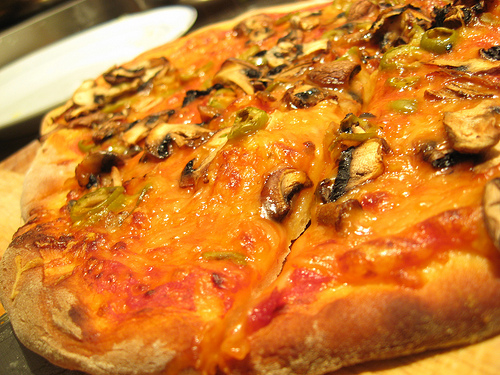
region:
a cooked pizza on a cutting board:
[26, 2, 496, 372]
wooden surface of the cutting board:
[378, 357, 497, 371]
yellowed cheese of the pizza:
[144, 192, 255, 300]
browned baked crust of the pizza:
[243, 289, 499, 353]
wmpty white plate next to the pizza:
[1, 3, 191, 111]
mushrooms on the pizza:
[261, 108, 499, 211]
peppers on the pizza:
[376, 25, 464, 104]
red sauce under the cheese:
[83, 251, 218, 320]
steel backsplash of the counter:
[0, 10, 88, 49]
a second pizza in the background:
[22, 18, 335, 143]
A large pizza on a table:
[21, 21, 471, 338]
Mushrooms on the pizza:
[18, 24, 478, 372]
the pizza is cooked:
[35, 21, 483, 363]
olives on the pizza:
[24, 81, 302, 202]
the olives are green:
[217, 114, 271, 141]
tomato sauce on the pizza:
[161, 241, 316, 316]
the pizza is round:
[51, 53, 498, 340]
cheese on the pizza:
[162, 197, 309, 301]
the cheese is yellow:
[117, 130, 251, 300]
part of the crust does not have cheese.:
[352, 300, 449, 325]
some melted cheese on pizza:
[163, 153, 265, 273]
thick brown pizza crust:
[8, 231, 179, 356]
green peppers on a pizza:
[48, 143, 214, 243]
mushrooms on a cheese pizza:
[258, 119, 423, 243]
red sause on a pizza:
[129, 199, 465, 334]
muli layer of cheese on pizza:
[173, 7, 388, 289]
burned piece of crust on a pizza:
[14, 173, 99, 279]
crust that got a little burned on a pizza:
[316, 248, 476, 358]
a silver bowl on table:
[0, 0, 242, 137]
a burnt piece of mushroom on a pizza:
[262, 134, 459, 291]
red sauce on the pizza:
[68, 237, 230, 321]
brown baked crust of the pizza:
[236, 284, 466, 371]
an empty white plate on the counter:
[11, 9, 176, 119]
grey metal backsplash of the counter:
[1, 5, 113, 40]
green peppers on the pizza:
[368, 41, 431, 121]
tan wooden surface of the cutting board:
[341, 345, 499, 373]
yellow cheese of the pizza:
[140, 186, 265, 259]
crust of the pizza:
[223, 205, 498, 373]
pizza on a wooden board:
[1, 0, 496, 369]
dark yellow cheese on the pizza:
[44, 87, 362, 322]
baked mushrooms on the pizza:
[262, 163, 310, 222]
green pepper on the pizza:
[419, 24, 458, 52]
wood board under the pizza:
[346, 305, 498, 370]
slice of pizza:
[1, 84, 369, 369]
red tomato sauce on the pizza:
[248, 261, 322, 331]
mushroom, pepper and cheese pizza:
[18, 0, 494, 371]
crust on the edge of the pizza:
[0, 202, 185, 367]